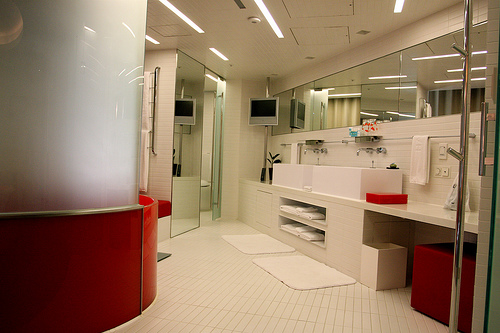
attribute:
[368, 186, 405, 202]
box — red, Closed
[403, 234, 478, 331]
seat — red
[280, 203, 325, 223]
towels — Folded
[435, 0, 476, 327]
pole — Metal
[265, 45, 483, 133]
mirror — top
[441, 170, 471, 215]
bag — Plastic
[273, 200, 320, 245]
towels — Folded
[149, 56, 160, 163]
towel rack — Metal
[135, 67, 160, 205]
towel rack — metal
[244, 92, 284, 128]
monitor — Video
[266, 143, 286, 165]
plant — small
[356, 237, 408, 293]
trash — white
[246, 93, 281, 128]
monitor — off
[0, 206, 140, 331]
wall — red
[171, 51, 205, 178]
mirror — large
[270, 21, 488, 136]
mirror — large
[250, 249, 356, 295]
rug — rectangular, white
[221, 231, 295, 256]
rug — rectangular, white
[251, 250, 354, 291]
rug — white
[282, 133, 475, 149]
rack — chrome, towel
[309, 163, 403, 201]
sink — elevated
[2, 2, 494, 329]
bathroom — white, red